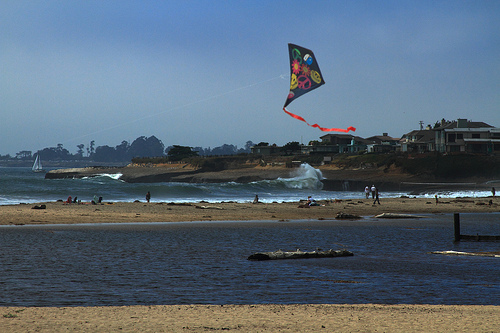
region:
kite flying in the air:
[272, 33, 364, 152]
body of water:
[91, 241, 226, 293]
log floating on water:
[245, 239, 375, 281]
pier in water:
[449, 208, 499, 248]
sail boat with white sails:
[25, 146, 48, 178]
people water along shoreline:
[355, 182, 383, 207]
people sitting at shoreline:
[65, 191, 118, 208]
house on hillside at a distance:
[306, 123, 376, 161]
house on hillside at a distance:
[395, 111, 498, 190]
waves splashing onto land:
[259, 152, 337, 201]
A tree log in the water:
[249, 244, 361, 265]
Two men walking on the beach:
[356, 181, 384, 206]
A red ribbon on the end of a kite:
[279, 108, 360, 138]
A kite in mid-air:
[266, 39, 330, 114]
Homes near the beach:
[289, 116, 499, 164]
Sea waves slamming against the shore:
[190, 162, 331, 191]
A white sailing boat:
[31, 154, 51, 175]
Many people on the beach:
[28, 188, 406, 213]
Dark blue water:
[0, 213, 496, 306]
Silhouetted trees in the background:
[2, 136, 261, 166]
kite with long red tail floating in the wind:
[267, 27, 373, 159]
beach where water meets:
[172, 290, 288, 330]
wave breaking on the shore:
[262, 160, 336, 196]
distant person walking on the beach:
[366, 185, 391, 210]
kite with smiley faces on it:
[280, 37, 334, 116]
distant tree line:
[80, 128, 159, 170]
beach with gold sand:
[100, 205, 153, 219]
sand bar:
[242, 243, 364, 270]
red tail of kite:
[277, 105, 372, 143]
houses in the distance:
[319, 129, 441, 169]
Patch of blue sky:
[4, 14, 217, 57]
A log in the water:
[233, 235, 363, 265]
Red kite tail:
[273, 108, 365, 135]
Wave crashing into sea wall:
[193, 137, 353, 194]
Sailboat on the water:
[10, 136, 67, 203]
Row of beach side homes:
[240, 110, 498, 199]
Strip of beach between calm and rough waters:
[2, 171, 497, 230]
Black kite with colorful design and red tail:
[276, 32, 373, 137]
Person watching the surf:
[123, 171, 208, 204]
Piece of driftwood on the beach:
[183, 194, 225, 217]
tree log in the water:
[224, 230, 369, 284]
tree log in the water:
[226, 220, 376, 260]